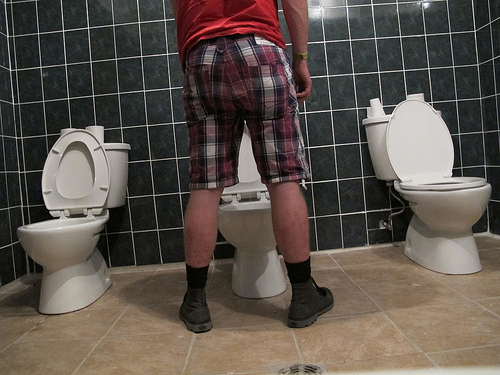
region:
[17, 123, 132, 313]
a white porcelain toilet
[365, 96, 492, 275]
a white porcelain toilet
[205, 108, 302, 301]
a white porcelain toilet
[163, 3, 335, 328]
a man is using a toilet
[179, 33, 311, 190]
a man's plaid shorts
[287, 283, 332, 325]
a man's dark colored shoe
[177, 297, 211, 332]
a man's dark colored shoe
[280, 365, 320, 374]
a drain in the dloor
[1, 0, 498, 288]
black tiles on a wall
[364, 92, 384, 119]
a roll of toilet paper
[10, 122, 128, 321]
the toilet in the bathroom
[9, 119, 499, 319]
the line of white toilets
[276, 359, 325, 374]
the drain on the ground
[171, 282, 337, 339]
the balck boots on the feet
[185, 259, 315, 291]
the balck socks on the feet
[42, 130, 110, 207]
the seat of the toilet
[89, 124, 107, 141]
the roll of toilet paper on the tank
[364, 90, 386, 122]
the tilting toilet paper roll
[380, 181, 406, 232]
the hose to the toilet tank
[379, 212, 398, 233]
the water pipe into the wall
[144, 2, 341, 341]
The bottom half of a person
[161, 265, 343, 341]
Person is wearing gray shoes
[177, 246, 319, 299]
Person is wearing black socks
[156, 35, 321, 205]
Person is wearing shorts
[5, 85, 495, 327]
Two white toilets in the foreground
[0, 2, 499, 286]
The walls are made up of black tiles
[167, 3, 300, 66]
Person is wearing a red shirt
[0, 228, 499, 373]
The ground is made up of tan colored tiles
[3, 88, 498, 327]
Toilet seats are up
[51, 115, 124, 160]
Toilet paper rolls are on top of the toilet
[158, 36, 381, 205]
a man wearing shorts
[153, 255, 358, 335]
a man wearing shoes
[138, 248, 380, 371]
shoes of the person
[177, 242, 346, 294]
a man wearing socks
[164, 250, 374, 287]
socks of the man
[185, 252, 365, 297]
socks to the legs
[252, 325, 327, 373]
a black object in floor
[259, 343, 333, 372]
a black object in ground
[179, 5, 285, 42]
a man wearing red shirt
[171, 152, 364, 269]
legs of the person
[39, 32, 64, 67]
black tile on bathroom wall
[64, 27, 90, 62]
black tile on bathroom wall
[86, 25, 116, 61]
black tile on bathroom wall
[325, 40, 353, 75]
black tile on bathroom wall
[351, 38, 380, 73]
black tile on bathroom wallblack tile on bathroom wall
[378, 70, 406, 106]
black tile on bathroom wall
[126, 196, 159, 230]
black tile on bathroom wall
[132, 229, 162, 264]
black tile on bathroom wall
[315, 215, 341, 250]
black tile on bathroom wall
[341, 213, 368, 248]
black tile on bathroom wall